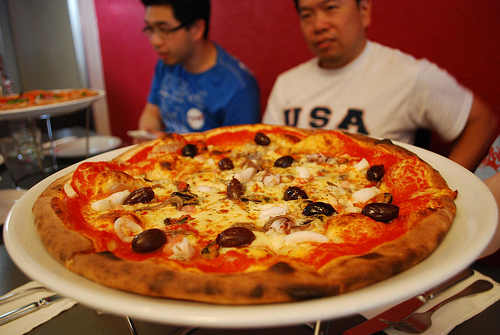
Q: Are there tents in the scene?
A: No, there are no tents.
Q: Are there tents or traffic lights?
A: No, there are no tents or traffic lights.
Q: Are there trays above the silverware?
A: Yes, there is a tray above the silverware.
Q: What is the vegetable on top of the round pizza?
A: The vegetable is an olive.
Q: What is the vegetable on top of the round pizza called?
A: The vegetable is an olive.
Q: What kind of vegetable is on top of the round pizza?
A: The vegetable is an olive.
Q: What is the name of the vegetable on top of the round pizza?
A: The vegetable is an olive.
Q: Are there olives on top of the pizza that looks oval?
A: Yes, there is an olive on top of the pizza.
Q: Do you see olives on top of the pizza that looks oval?
A: Yes, there is an olive on top of the pizza.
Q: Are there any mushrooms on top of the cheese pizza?
A: No, there is an olive on top of the pizza.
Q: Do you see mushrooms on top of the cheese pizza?
A: No, there is an olive on top of the pizza.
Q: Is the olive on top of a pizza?
A: Yes, the olive is on top of a pizza.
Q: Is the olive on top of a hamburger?
A: No, the olive is on top of a pizza.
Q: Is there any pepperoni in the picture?
A: No, there is no pepperoni.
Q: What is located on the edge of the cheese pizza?
A: The crust is on the edge of the pizza.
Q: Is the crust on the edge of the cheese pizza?
A: Yes, the crust is on the edge of the pizza.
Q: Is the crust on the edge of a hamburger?
A: No, the crust is on the edge of the pizza.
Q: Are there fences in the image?
A: No, there are no fences.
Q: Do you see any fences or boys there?
A: No, there are no fences or boys.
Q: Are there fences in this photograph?
A: No, there are no fences.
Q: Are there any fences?
A: No, there are no fences.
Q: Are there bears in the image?
A: No, there are no bears.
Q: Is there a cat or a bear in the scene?
A: No, there are no bears or cats.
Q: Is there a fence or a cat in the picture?
A: No, there are no fences or cats.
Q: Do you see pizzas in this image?
A: Yes, there is a pizza.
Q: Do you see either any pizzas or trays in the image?
A: Yes, there is a pizza.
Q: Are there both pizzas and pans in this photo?
A: No, there is a pizza but no pans.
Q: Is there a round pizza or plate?
A: Yes, there is a round pizza.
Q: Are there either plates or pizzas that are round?
A: Yes, the pizza is round.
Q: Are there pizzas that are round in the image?
A: Yes, there is a round pizza.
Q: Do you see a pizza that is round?
A: Yes, there is a pizza that is round.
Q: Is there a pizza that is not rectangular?
A: Yes, there is a round pizza.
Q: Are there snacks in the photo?
A: No, there are no snacks.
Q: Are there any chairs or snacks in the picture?
A: No, there are no snacks or chairs.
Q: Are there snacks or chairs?
A: No, there are no snacks or chairs.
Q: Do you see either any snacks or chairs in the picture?
A: No, there are no snacks or chairs.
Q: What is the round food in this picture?
A: The food is a pizza.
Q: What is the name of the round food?
A: The food is a pizza.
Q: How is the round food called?
A: The food is a pizza.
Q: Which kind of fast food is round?
A: The fast food is a pizza.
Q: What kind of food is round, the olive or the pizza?
A: The pizza is round.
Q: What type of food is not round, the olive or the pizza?
A: The olive is not round.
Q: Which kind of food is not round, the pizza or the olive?
A: The olive is not round.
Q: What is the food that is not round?
A: The food is an olive.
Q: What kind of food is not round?
A: The food is an olive.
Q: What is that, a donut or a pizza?
A: That is a pizza.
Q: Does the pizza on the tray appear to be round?
A: Yes, the pizza is round.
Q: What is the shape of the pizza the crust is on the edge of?
A: The pizza is round.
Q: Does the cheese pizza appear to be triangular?
A: No, the pizza is round.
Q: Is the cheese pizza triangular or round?
A: The pizza is round.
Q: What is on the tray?
A: The pizza is on the tray.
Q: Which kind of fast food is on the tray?
A: The food is a pizza.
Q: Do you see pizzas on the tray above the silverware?
A: Yes, there is a pizza on the tray.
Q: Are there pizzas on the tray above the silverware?
A: Yes, there is a pizza on the tray.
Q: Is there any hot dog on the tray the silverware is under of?
A: No, there is a pizza on the tray.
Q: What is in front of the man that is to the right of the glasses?
A: The pizza is in front of the man.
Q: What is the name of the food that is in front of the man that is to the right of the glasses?
A: The food is a pizza.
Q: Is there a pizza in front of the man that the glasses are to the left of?
A: Yes, there is a pizza in front of the man.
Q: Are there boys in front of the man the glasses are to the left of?
A: No, there is a pizza in front of the man.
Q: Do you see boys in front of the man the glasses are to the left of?
A: No, there is a pizza in front of the man.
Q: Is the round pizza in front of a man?
A: Yes, the pizza is in front of a man.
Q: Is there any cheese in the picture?
A: Yes, there is cheese.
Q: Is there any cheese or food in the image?
A: Yes, there is cheese.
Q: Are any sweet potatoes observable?
A: No, there are no sweet potatoes.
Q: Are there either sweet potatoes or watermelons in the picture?
A: No, there are no sweet potatoes or watermelons.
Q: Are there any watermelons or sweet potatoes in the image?
A: No, there are no sweet potatoes or watermelons.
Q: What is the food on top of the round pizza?
A: The food is cheese.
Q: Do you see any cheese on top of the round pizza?
A: Yes, there is cheese on top of the pizza.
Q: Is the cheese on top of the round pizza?
A: Yes, the cheese is on top of the pizza.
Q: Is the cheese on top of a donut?
A: No, the cheese is on top of the pizza.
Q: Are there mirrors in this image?
A: No, there are no mirrors.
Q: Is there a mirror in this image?
A: No, there are no mirrors.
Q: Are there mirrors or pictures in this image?
A: No, there are no mirrors or pictures.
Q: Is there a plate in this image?
A: Yes, there is a plate.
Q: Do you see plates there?
A: Yes, there is a plate.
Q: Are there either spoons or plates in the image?
A: Yes, there is a plate.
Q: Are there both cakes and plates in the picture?
A: No, there is a plate but no cakes.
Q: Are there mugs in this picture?
A: No, there are no mugs.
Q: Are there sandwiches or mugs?
A: No, there are no mugs or sandwiches.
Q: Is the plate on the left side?
A: Yes, the plate is on the left of the image.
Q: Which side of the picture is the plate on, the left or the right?
A: The plate is on the left of the image.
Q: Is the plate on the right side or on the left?
A: The plate is on the left of the image.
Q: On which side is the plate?
A: The plate is on the left of the image.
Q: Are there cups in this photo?
A: No, there are no cups.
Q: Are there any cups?
A: No, there are no cups.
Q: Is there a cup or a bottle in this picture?
A: No, there are no cups or bottles.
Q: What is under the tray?
A: The silverware is under the tray.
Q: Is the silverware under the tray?
A: Yes, the silverware is under the tray.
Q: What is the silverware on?
A: The silverware is on the napkin.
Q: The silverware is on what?
A: The silverware is on the napkin.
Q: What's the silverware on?
A: The silverware is on the napkin.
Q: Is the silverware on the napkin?
A: Yes, the silverware is on the napkin.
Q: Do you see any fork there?
A: Yes, there is a fork.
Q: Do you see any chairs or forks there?
A: Yes, there is a fork.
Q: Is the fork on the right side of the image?
A: Yes, the fork is on the right of the image.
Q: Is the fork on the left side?
A: No, the fork is on the right of the image.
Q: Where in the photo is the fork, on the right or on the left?
A: The fork is on the right of the image.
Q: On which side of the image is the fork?
A: The fork is on the right of the image.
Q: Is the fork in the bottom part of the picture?
A: Yes, the fork is in the bottom of the image.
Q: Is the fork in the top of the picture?
A: No, the fork is in the bottom of the image.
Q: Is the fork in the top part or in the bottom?
A: The fork is in the bottom of the image.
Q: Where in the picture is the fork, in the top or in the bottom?
A: The fork is in the bottom of the image.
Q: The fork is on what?
A: The fork is on the napkin.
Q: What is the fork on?
A: The fork is on the napkin.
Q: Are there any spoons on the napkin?
A: No, there is a fork on the napkin.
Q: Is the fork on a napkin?
A: Yes, the fork is on a napkin.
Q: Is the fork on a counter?
A: No, the fork is on a napkin.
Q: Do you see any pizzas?
A: Yes, there is a pizza.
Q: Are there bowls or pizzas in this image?
A: Yes, there is a pizza.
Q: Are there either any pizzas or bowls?
A: Yes, there is a pizza.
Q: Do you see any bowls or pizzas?
A: Yes, there is a pizza.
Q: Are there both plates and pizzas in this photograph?
A: Yes, there are both a pizza and a plate.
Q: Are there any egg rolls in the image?
A: No, there are no egg rolls.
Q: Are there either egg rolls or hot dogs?
A: No, there are no egg rolls or hot dogs.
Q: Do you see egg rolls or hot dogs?
A: No, there are no egg rolls or hot dogs.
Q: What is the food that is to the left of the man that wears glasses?
A: The food is a pizza.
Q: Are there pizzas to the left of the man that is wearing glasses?
A: Yes, there is a pizza to the left of the man.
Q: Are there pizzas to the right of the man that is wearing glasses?
A: No, the pizza is to the left of the man.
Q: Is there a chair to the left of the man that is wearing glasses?
A: No, there is a pizza to the left of the man.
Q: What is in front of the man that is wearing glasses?
A: The pizza is in front of the man.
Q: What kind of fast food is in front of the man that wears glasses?
A: The food is a pizza.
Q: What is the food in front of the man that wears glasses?
A: The food is a pizza.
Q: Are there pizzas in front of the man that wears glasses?
A: Yes, there is a pizza in front of the man.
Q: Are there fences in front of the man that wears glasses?
A: No, there is a pizza in front of the man.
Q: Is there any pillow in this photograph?
A: No, there are no pillows.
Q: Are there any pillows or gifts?
A: No, there are no pillows or gifts.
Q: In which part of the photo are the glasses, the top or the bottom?
A: The glasses are in the top of the image.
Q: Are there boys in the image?
A: No, there are no boys.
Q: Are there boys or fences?
A: No, there are no boys or fences.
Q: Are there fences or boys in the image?
A: No, there are no boys or fences.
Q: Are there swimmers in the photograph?
A: No, there are no swimmers.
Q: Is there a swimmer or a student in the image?
A: No, there are no swimmers or students.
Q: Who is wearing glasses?
A: The man is wearing glasses.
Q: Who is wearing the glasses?
A: The man is wearing glasses.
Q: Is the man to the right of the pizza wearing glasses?
A: Yes, the man is wearing glasses.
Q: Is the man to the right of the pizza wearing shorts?
A: No, the man is wearing glasses.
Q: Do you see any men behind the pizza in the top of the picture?
A: Yes, there is a man behind the pizza.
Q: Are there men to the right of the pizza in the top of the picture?
A: Yes, there is a man to the right of the pizza.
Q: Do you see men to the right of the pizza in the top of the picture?
A: Yes, there is a man to the right of the pizza.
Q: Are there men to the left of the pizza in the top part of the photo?
A: No, the man is to the right of the pizza.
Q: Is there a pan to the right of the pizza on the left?
A: No, there is a man to the right of the pizza.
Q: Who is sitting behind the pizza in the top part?
A: The man is sitting behind the pizza.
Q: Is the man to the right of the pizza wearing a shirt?
A: Yes, the man is wearing a shirt.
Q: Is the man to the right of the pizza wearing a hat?
A: No, the man is wearing a shirt.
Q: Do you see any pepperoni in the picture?
A: No, there is no pepperoni.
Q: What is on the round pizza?
A: The tomato sauce is on the pizza.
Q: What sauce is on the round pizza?
A: The sauce is tomato sauce.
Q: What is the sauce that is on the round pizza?
A: The sauce is tomato sauce.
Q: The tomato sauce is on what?
A: The tomato sauce is on the pizza.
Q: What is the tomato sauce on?
A: The tomato sauce is on the pizza.